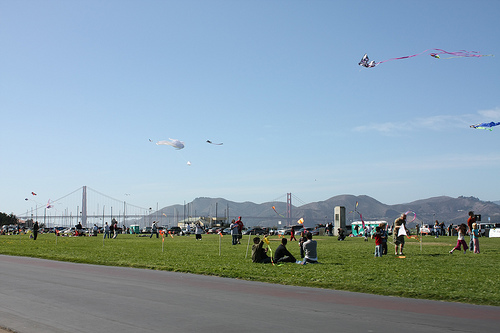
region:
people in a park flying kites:
[52, 43, 491, 282]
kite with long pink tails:
[341, 42, 490, 75]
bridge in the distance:
[10, 178, 333, 223]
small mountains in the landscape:
[129, 192, 497, 229]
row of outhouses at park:
[349, 216, 390, 238]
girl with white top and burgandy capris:
[450, 221, 472, 255]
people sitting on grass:
[242, 232, 324, 268]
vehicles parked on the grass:
[40, 219, 87, 238]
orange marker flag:
[155, 227, 172, 256]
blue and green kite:
[465, 117, 498, 133]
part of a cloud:
[356, 107, 383, 144]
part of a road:
[183, 266, 220, 296]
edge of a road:
[301, 275, 329, 297]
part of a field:
[385, 256, 405, 275]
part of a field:
[300, 264, 317, 280]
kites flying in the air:
[24, 46, 497, 209]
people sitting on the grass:
[249, 232, 318, 264]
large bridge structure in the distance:
[21, 186, 326, 224]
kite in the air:
[355, 50, 417, 68]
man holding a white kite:
[394, 210, 409, 260]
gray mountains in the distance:
[134, 193, 499, 228]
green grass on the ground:
[0, 231, 497, 307]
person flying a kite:
[196, 221, 204, 239]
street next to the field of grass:
[4, 247, 499, 332]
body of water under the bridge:
[29, 216, 139, 227]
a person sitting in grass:
[249, 235, 272, 262]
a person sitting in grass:
[270, 236, 295, 266]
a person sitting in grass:
[298, 231, 318, 265]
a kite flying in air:
[352, 51, 424, 68]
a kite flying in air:
[148, 137, 184, 150]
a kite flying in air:
[200, 137, 224, 147]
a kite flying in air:
[470, 117, 499, 132]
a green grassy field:
[3, 227, 497, 306]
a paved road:
[0, 252, 493, 330]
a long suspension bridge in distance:
[0, 184, 376, 231]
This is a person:
[270, 235, 298, 274]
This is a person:
[250, 239, 273, 267]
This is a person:
[388, 209, 410, 261]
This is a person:
[445, 215, 466, 262]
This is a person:
[302, 233, 324, 266]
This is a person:
[191, 214, 210, 246]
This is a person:
[227, 211, 250, 248]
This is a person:
[335, 220, 346, 244]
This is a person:
[285, 221, 298, 242]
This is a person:
[445, 215, 456, 240]